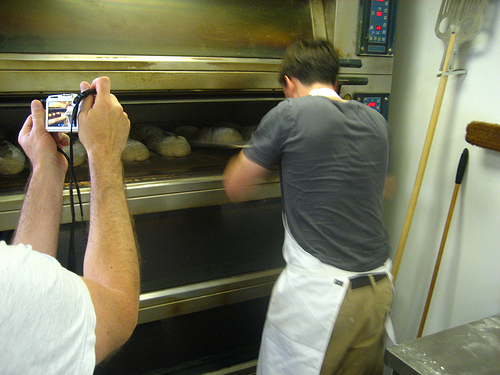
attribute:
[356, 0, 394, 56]
oven controls — digital controls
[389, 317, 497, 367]
counter — dirty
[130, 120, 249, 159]
bread — loaves